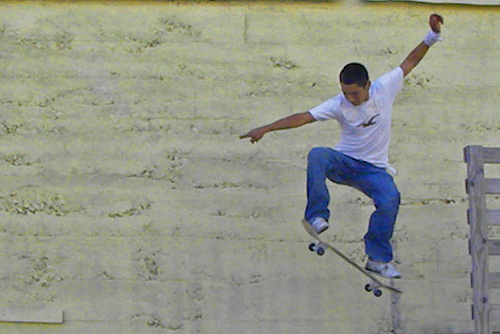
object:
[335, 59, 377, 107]
head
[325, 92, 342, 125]
shoulder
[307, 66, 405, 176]
shirt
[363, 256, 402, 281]
skate shoe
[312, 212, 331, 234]
skate shoe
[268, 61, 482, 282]
man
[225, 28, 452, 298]
skateboarder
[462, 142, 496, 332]
pallet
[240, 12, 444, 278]
guy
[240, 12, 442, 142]
arms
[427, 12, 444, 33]
hand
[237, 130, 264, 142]
hand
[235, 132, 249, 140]
finger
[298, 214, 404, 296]
skateboard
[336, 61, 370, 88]
hair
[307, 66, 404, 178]
t-shirt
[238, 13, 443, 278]
boy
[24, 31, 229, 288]
white wall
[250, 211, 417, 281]
foot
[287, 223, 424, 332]
skateboard trick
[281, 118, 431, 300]
skating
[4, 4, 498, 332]
wall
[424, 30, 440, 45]
sweatband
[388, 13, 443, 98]
left arm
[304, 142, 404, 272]
legs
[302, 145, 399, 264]
jeans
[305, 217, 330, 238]
shoe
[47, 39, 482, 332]
air